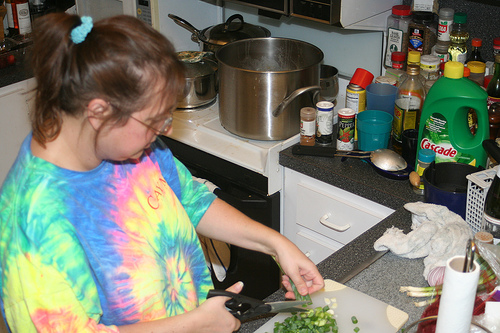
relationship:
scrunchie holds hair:
[71, 12, 97, 48] [28, 7, 192, 116]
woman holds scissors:
[3, 14, 325, 327] [206, 270, 338, 322]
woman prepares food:
[3, 14, 325, 327] [269, 264, 351, 331]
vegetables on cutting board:
[277, 290, 359, 331] [244, 279, 413, 331]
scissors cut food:
[207, 290, 306, 330] [268, 283, 359, 331]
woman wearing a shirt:
[3, 14, 325, 327] [0, 133, 219, 333]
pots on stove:
[155, 2, 348, 147] [146, 3, 326, 278]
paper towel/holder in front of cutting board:
[430, 238, 484, 331] [244, 279, 413, 331]